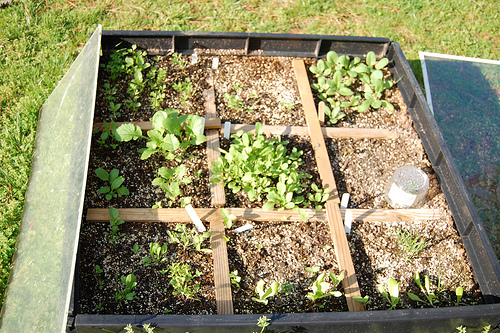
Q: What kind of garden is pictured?
A: A container garden.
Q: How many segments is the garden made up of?
A: Nine.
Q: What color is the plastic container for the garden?
A: Black.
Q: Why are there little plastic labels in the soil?
A: For plant identification.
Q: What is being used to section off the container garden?
A: Strips of wood.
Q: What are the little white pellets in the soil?
A: Fertilizer.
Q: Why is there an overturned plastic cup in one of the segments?
A: To protect a seedling.